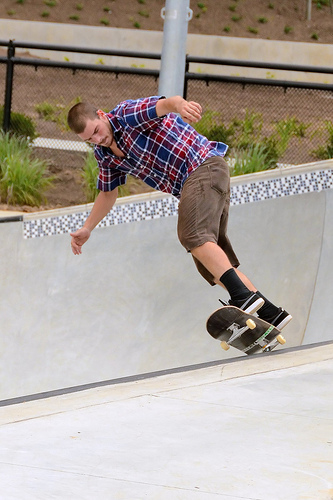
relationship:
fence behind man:
[4, 37, 332, 132] [66, 93, 290, 339]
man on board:
[66, 93, 290, 339] [206, 303, 290, 365]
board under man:
[206, 303, 290, 365] [66, 93, 290, 339]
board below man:
[206, 303, 290, 365] [66, 93, 290, 339]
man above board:
[66, 93, 290, 339] [206, 303, 290, 365]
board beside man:
[206, 303, 290, 365] [66, 93, 290, 339]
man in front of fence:
[66, 93, 290, 339] [4, 37, 332, 132]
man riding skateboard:
[70, 93, 292, 327] [205, 304, 287, 358]